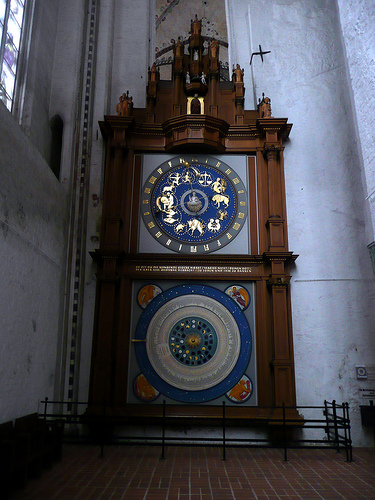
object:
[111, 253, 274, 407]
board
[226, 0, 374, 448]
wall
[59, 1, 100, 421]
pillar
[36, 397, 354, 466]
fence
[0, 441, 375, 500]
floor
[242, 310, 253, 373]
rim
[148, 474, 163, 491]
square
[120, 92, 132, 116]
statue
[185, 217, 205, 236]
decoration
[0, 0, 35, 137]
window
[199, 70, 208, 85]
figure